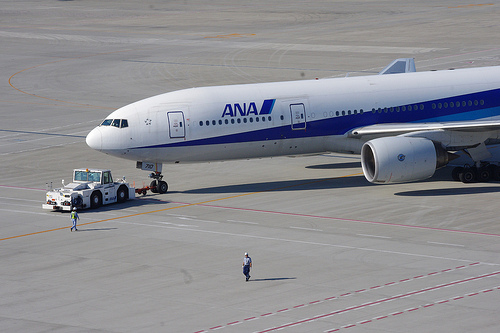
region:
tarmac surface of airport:
[3, 2, 498, 329]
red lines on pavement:
[294, 252, 497, 331]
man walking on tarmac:
[242, 252, 253, 284]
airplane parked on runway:
[84, 58, 498, 193]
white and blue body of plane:
[85, 60, 497, 184]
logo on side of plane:
[221, 97, 276, 117]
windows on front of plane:
[101, 119, 130, 129]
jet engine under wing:
[360, 134, 446, 184]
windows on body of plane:
[322, 99, 489, 121]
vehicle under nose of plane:
[43, 167, 131, 212]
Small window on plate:
[190, 112, 207, 133]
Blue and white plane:
[51, 62, 492, 286]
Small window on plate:
[204, 115, 214, 132]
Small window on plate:
[210, 113, 222, 133]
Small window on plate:
[222, 115, 242, 129]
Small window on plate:
[240, 114, 254, 124]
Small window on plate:
[254, 113, 279, 123]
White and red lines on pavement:
[191, 276, 476, 323]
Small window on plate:
[334, 105, 366, 119]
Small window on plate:
[368, 103, 430, 122]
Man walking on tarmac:
[235, 247, 255, 282]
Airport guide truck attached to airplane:
[36, 161, 153, 216]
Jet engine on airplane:
[354, 130, 453, 190]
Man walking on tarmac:
[63, 201, 80, 230]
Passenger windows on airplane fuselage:
[195, 89, 493, 136]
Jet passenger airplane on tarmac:
[82, 55, 498, 198]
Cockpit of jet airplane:
[92, 110, 133, 134]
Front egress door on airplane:
[162, 105, 188, 141]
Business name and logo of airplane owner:
[215, 95, 277, 121]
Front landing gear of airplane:
[142, 172, 172, 194]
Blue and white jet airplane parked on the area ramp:
[85, 58, 498, 183]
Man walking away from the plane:
[238, 247, 255, 282]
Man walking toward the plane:
[66, 204, 82, 233]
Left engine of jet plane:
[361, 135, 437, 185]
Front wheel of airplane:
[147, 179, 167, 194]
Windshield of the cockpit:
[98, 117, 129, 127]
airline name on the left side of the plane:
[218, 99, 262, 117]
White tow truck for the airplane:
[44, 169, 134, 211]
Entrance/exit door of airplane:
[165, 109, 187, 137]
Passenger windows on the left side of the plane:
[197, 103, 391, 128]